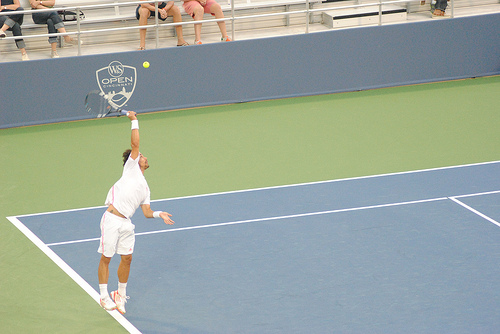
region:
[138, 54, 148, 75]
The ball is yellow.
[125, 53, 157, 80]
The ball is moving through the air.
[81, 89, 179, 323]
He is swinging the raquet.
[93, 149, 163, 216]
He is wearing a white shirt.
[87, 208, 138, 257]
He is wearing white shorts.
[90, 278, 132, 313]
He is wearing white shoes.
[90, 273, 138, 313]
He is wearing white socks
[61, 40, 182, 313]
He is playing tennis.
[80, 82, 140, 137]
He is holding a racket.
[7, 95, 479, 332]
The court is blue and green.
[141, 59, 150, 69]
a tennis ball in the air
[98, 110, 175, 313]
a tennis player wearing white wristbands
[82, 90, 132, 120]
a tennis racket being swung by a tennis player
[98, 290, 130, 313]
red and white shoes on a tennis player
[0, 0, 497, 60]
people are sitting on bleachers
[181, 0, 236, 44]
a person wearing peach shorts in the bleachers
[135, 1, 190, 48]
a person wearing black shorts in the bleachers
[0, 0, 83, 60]
two women wearing jeans sitting the same way in the bleachers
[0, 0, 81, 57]
two women with white shoes and silver bracelets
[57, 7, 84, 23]
a black and grey bag on the bleachers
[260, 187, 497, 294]
the court is blue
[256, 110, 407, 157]
the court is green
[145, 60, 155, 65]
the ball is in the air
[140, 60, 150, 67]
the ball is green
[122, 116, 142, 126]
the wrist band is white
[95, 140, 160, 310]
the guy is in the air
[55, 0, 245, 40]
thespectators are seated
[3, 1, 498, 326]
the game being played is tennis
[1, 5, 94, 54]
the legs are crossed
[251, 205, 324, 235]
the line is white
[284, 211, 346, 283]
part of a court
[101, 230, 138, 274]
part of a short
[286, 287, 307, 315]
part of a court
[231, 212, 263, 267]
part of a court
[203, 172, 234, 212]
part of a court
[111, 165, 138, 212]
part of a shirt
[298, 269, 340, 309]
part of a court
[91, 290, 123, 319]
part of a shoe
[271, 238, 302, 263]
part of a court